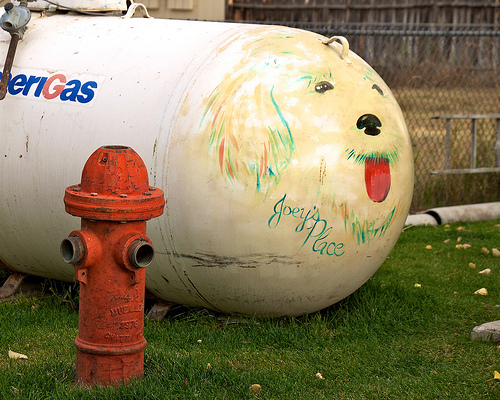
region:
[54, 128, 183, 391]
this is a fire hydrant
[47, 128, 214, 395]
a fire hydrant on a lawn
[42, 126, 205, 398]
a red fire hydrant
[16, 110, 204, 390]
the fire hydrant is red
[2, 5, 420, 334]
this is a large gas tank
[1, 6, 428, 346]
a large propane tank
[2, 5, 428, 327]
a large tank of propane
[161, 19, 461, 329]
the end of the tank is painted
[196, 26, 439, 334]
the face of a dog painted on the tank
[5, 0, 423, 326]
a white tank that has been painted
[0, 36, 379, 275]
white gas tank on grass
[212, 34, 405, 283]
dog's face on tank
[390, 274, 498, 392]
green grass around tank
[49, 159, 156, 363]
red hydrant near tank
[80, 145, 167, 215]
red cap on hydrant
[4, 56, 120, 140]
red and blue logo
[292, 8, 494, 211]
grey fence behind tank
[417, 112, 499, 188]
brown ladder on chain link fence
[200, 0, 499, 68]
wooden fence in distance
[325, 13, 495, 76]
wooden fence is brown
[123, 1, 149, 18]
handle on the tank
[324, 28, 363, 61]
handle on the tank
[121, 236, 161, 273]
outlet on the hydrant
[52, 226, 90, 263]
outlet on the hydrant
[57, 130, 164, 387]
hydrant in the grass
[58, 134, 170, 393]
hydrant next to gas tank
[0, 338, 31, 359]
leaf in the grass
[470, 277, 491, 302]
leaf in the grass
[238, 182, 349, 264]
graffiti on the tank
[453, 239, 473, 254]
leaves in the grass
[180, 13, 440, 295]
a dog is on the pole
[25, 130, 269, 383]
the hydrant is red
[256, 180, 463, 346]
green writing on the pole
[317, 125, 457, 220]
the dog has a tongue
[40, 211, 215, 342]
the hydrant has holes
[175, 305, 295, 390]
leaves are in the grass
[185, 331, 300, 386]
the grass is on the ground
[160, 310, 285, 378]
the grass is overgrown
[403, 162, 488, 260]
a metal pole is cracked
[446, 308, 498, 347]
a rock is on the ground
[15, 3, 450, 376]
Fire hydrant standing next to gas tank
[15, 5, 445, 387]
Gas tank standing next to fire hydrant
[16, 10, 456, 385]
Red fire hydrant standing next to white gas tank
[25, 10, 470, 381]
Red fire hydrant on grass standing next to white tank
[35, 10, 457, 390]
Large gas tank with dog face next to fire hydrant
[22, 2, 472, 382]
Large fire hydrant painted with dog face on grass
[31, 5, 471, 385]
Large gas tank painted with dog face and signature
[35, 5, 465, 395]
White tank with fence in background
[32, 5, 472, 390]
Fire hydrant sit next to tank before rain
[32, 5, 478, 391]
Gas tank sitting in grass next to fire hydrant